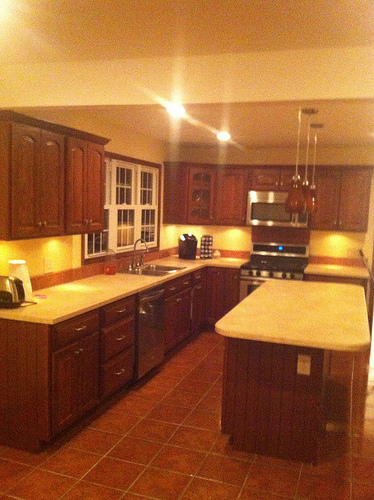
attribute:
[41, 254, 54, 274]
outlet — white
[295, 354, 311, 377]
outlet — white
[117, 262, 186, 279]
sink — stainless steel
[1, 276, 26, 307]
toaster — stainless steel, silver, black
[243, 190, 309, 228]
microwave — stainless steel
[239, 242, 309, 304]
stove — stainless steel, black, stove/oven combo, silver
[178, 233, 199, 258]
coffee maker — single cup maker, black, single serve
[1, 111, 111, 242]
cabinet — wooden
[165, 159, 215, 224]
cabinet — wooden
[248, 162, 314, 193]
cabinet — wooden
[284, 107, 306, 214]
light — pendant, brown, silver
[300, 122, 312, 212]
light — pendant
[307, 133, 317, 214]
light — pendant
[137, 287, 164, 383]
dishwasher — stainless steel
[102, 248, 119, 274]
bottle — dishwasher liquid, plastic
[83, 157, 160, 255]
windows — white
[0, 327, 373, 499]
floor — reddish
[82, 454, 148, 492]
floor tile — reddish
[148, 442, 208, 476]
floor tile — reddish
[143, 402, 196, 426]
floor tile — reddish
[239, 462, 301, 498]
floor tile — reddish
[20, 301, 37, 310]
cord — black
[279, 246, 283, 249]
clock — blurry, blue, led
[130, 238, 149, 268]
faucet — stainless steel, curved